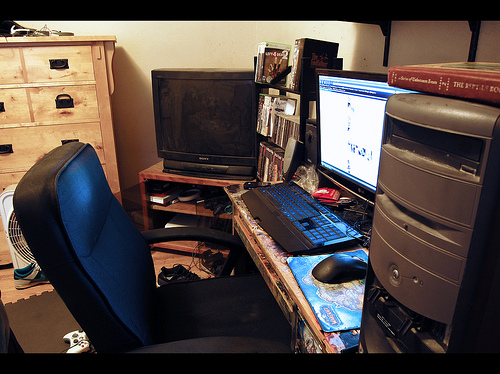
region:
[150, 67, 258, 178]
Tube television set on wooden TV stand.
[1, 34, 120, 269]
Blonde wood chest of drawers.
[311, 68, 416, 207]
Powered up computer monitor.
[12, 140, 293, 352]
Black leather swivel desk chair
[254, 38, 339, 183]
Media rack with video games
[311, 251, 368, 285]
Black computer mouse on mouse pad.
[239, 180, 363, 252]
Computer keyboard with blue keys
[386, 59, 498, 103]
Hard bound book with red spine.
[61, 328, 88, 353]
White Xbox controller behind chair.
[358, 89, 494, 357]
Black CPU tower in foreground.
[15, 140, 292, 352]
A black desk chair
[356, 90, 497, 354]
A black desk top computer tower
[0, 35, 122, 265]
A light wood dresser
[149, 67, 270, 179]
A black tv set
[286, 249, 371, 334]
A mouse pad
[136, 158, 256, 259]
A wooden tv stand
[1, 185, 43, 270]
A white box fan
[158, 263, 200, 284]
A black athletic shoe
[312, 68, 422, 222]
A computer monitor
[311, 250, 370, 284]
A black computer mouse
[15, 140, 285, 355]
very cushioned office chair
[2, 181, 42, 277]
white fan sits on floor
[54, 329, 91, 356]
video console remote control on floor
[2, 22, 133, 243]
wood dresser against wall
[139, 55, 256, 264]
television on wood TV stand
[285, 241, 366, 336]
computer mouse on a mouse pad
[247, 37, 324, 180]
shelves of movies and video games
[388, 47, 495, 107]
hard covered book on top of computer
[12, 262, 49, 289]
blue, white, and black sneaker on floor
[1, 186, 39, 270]
part of a white fan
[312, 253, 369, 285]
a black computer mouse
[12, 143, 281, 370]
a black computer chair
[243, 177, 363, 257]
a black computer keyboard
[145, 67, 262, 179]
part of a black t.v.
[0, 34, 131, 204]
part of a brown dresser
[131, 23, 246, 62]
part of a white wall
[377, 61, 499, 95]
a red book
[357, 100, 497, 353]
part of a computer cpu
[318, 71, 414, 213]
part of a computer monitor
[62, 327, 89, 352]
A video game controller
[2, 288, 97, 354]
A black floor mat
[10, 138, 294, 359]
A black rolling desk chair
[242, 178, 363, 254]
A black keyboard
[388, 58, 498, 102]
A hard cover book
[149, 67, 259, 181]
A black tv set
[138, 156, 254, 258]
An open shelf tv stand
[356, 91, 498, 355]
A desk top computer tower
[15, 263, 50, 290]
A blue and white sneaker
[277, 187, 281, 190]
a key on a keyboard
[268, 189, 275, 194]
a key on a keyboard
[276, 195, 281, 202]
a key on a keyboard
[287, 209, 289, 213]
a key on a keyboard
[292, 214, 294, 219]
a key on a keyboard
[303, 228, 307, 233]
a key on a keyboard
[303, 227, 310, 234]
a key on a keyboard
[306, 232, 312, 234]
a key on a keyboard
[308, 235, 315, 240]
a key on a keyboard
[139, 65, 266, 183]
A television on a stand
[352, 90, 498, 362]
A tall black computer case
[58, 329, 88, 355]
A white Xbox controller